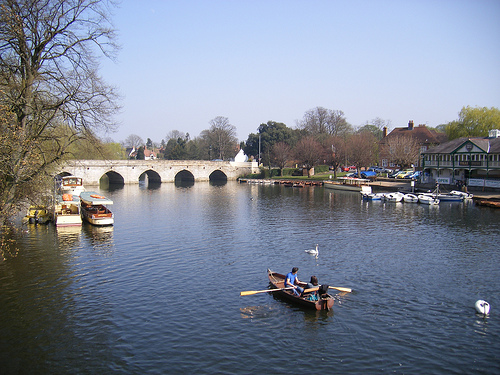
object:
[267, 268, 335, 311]
boat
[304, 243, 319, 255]
bird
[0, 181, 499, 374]
water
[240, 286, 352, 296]
two paddles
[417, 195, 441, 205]
boats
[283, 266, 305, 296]
man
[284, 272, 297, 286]
blue shirt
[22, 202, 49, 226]
boat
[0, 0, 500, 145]
sky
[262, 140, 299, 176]
trees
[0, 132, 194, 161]
distance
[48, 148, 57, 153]
leaves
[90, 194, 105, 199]
buoy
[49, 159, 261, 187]
bridge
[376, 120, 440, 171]
house